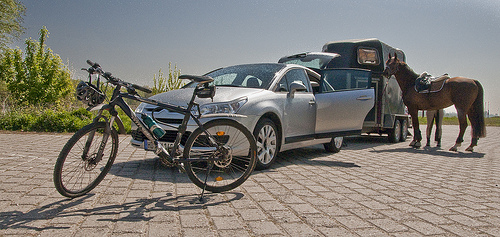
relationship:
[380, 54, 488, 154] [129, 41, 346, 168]
horse next to car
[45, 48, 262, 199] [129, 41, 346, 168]
bicycle in front of car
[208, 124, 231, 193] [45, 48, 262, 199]
lights on bicycle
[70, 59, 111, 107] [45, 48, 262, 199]
helmet hanging on bicycle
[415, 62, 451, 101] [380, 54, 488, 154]
saddle on horse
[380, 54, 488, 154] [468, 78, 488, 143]
horse has a tail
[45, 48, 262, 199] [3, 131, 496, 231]
bicycle on pavement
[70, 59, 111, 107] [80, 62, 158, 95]
helmet hanging on handlebars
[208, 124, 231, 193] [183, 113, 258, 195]
lights on wheel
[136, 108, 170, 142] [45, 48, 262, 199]
bottle attached to bicycle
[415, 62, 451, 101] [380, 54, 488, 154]
saddle on top of horse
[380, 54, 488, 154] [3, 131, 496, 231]
horse standing on pavement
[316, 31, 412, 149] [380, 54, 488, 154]
trailer for horse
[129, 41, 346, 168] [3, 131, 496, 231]
car on pavement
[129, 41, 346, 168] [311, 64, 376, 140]
car has open door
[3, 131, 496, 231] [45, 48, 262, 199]
pavement under bicycle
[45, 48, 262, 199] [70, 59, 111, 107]
bicycle has helmet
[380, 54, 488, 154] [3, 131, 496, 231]
horse on pavement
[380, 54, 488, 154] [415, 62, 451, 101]
horse under a saddle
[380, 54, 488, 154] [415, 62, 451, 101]
horse has a saddle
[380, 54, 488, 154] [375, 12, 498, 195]
horse on right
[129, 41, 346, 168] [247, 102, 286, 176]
car has wheel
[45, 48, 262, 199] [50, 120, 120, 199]
bicycle has a tire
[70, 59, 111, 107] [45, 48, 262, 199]
helmet on bicycle